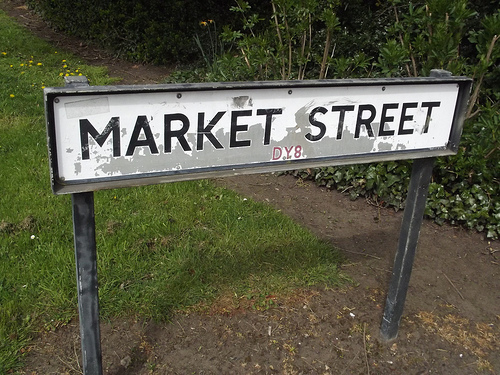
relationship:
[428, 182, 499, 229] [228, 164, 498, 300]
leaves on ground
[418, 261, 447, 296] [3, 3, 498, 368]
dirt on ground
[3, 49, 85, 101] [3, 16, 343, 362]
yellow flowers on grass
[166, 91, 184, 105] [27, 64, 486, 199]
bolt on sign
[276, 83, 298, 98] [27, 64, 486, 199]
bolt on sign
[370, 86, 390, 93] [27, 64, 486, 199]
bolt on sign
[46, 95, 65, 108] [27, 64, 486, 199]
bolt on sign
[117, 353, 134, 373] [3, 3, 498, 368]
rock on ground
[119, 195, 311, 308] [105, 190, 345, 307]
grass on ground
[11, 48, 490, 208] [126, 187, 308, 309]
sign on grass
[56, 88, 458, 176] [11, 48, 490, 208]
paint on sign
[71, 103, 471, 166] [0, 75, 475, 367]
writing on sign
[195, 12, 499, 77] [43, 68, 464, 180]
trees behind sign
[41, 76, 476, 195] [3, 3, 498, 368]
sign posted on ground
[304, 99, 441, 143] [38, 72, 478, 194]
writing on sign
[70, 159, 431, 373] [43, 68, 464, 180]
poles connecting sign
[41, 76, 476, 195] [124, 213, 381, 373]
sign has shadow